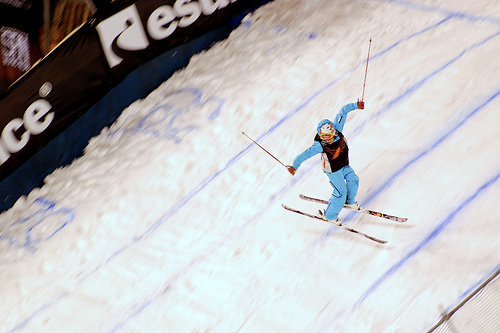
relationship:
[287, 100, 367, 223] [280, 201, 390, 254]
person on top of ski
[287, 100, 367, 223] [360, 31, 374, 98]
person holding ski pole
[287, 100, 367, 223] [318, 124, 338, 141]
person wearing helmet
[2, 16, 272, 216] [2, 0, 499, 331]
net beside snow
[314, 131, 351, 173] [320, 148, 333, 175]
suit has edge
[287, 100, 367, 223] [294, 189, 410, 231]
person has left ski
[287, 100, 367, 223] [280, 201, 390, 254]
person has ski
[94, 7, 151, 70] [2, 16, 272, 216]
company logo printed on net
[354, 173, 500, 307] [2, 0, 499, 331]
line in snow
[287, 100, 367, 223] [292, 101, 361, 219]
person wearing ski suit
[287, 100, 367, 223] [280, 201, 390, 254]
person wearing ski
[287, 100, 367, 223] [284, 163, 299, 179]
person wearing glove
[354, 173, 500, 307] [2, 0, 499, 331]
line painted in snow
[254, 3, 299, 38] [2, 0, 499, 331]
track in snow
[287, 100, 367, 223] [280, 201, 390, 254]
person sideways on ski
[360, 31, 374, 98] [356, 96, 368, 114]
ski pole held in hand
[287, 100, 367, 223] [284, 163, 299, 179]
person has glove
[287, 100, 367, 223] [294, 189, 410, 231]
person wearing left ski